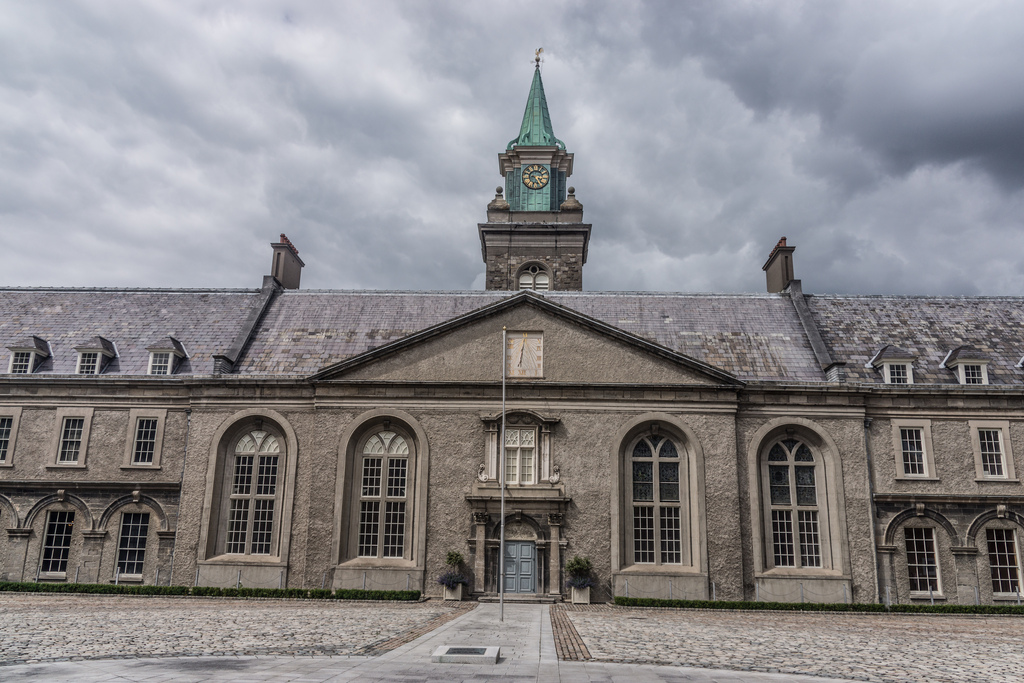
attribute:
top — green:
[501, 25, 590, 159]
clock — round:
[509, 155, 562, 197]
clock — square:
[492, 325, 590, 395]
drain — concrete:
[421, 634, 517, 676]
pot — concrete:
[438, 580, 478, 607]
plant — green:
[432, 535, 489, 607]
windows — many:
[17, 406, 1022, 605]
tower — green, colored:
[459, 55, 637, 300]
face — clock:
[522, 160, 548, 187]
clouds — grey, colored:
[16, 9, 1010, 303]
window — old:
[742, 422, 864, 589]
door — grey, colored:
[485, 504, 542, 604]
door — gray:
[486, 519, 553, 599]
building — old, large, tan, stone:
[0, 33, 1022, 610]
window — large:
[765, 424, 826, 574]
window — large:
[620, 420, 692, 570]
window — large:
[348, 415, 409, 563]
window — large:
[220, 415, 277, 554]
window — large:
[197, 418, 297, 555]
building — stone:
[37, 347, 986, 683]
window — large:
[748, 423, 848, 683]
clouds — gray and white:
[86, 105, 357, 261]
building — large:
[9, 164, 1021, 622]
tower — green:
[525, 205, 539, 219]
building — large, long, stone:
[26, 281, 1009, 604]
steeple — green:
[467, 74, 666, 379]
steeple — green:
[498, 49, 578, 216]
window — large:
[610, 408, 710, 583]